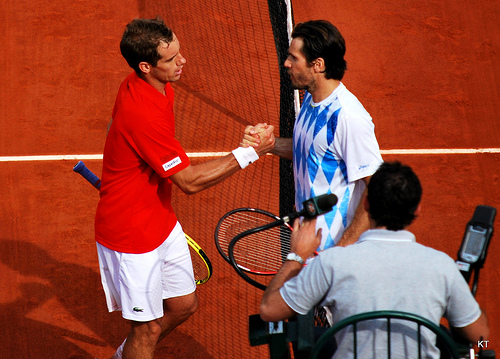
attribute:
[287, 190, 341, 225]
microphone — black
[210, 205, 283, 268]
racket — black, red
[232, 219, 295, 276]
racket — red, black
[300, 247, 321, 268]
racket — red, black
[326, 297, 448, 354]
chair — green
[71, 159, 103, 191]
handle — blue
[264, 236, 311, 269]
clock wrist — round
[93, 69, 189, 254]
shirt — red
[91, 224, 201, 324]
shorts — white